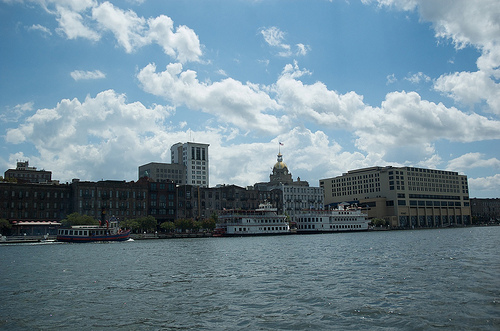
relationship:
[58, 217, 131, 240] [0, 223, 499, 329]
boat on water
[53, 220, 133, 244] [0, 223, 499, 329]
boat on water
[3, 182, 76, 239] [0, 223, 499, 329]
building near water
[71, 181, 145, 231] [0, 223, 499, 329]
building near water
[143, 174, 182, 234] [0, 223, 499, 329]
building near water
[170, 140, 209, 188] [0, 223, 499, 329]
building near water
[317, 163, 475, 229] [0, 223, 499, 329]
building near water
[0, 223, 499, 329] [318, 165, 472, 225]
water near building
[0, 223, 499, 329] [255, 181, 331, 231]
water near building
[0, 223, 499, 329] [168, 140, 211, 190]
water near building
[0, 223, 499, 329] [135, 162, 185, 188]
water near building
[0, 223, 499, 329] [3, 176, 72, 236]
water near building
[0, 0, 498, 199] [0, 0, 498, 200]
clouds in sky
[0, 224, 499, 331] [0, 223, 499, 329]
ripple in water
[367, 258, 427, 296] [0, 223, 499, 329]
ripple in water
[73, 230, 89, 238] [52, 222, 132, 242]
window on boat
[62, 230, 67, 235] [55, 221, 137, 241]
window on boat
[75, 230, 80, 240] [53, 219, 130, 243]
window on boat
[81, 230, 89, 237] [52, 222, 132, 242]
window on boat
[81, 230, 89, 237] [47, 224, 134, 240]
window on boat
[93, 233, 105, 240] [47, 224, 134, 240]
window on boat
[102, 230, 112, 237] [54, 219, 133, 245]
window on boat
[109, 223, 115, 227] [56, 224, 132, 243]
window on boat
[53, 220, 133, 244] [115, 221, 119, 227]
boat on window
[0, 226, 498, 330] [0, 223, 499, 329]
wave in water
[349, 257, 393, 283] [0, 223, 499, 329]
wave in water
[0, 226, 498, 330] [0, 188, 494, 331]
wave in water